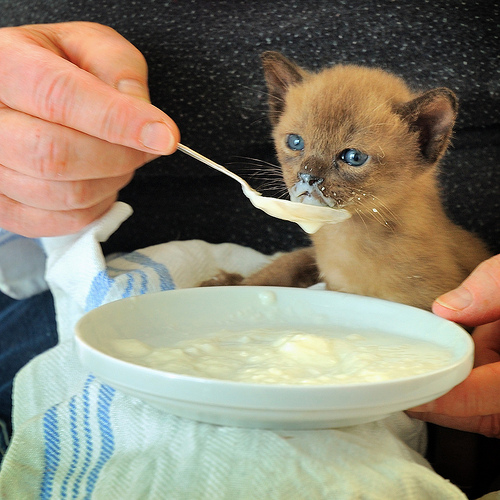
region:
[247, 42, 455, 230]
kitten with a messy face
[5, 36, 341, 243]
hand holding a spoon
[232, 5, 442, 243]
kitten being fed with spoon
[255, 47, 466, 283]
tan colored kitten with blue eyes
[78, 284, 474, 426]
bowl of white gruel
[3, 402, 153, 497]
white t-towel with blue stripes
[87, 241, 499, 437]
hand holding white bowl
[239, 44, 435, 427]
baby cat eating gruel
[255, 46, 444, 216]
kitten with messy face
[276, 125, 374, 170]
blue eyes of a kitten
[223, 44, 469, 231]
kitten eating some milk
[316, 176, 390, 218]
whiskers on the cat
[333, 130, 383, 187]
eye of the cat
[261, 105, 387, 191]
two eyes of the cat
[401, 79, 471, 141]
ear of the cat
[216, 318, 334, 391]
food in a bowl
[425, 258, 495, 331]
thumb of the person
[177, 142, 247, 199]
handle of the spoon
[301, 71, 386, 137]
top of the cat's head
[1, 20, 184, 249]
hand of a person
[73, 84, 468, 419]
an animal eating some food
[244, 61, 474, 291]
this animal is enjoying a meal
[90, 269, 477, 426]
this is some kind of cereal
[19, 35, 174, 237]
this is a hand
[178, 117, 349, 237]
this is a spoon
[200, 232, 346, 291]
the animal's arm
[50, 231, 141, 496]
a blue and white cloth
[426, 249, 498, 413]
fingers holding a bowl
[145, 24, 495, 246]
a dark gray shirt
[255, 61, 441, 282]
this animal is light brown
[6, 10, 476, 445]
A little baby kitten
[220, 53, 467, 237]
A brown baby kitten being fed with a spoon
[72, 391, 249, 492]
A white cloth with blue stripes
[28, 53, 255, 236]
A hand holding a plastic spoon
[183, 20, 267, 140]
Black spotted shirt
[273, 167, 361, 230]
A small kitten with milk on its mouth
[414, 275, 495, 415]
A hand holding a white dish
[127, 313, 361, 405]
A white saucer with kitten food in it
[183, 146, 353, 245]
A white plastic spoon with food on it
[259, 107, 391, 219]
A small kitten with blue gray eyes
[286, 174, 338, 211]
milk on kitten's face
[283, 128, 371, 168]
kitten's blue eyes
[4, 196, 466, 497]
blue and white dish towel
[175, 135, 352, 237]
spoon in man's hand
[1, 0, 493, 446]
man spoon-feeding kitten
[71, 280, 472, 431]
bowl of dairy mush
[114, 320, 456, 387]
dairy mush inside bowl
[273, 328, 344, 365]
clump of mush in middle of bowl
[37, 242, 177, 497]
blue stripes on white towel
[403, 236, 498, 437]
man's left hand holding bowl